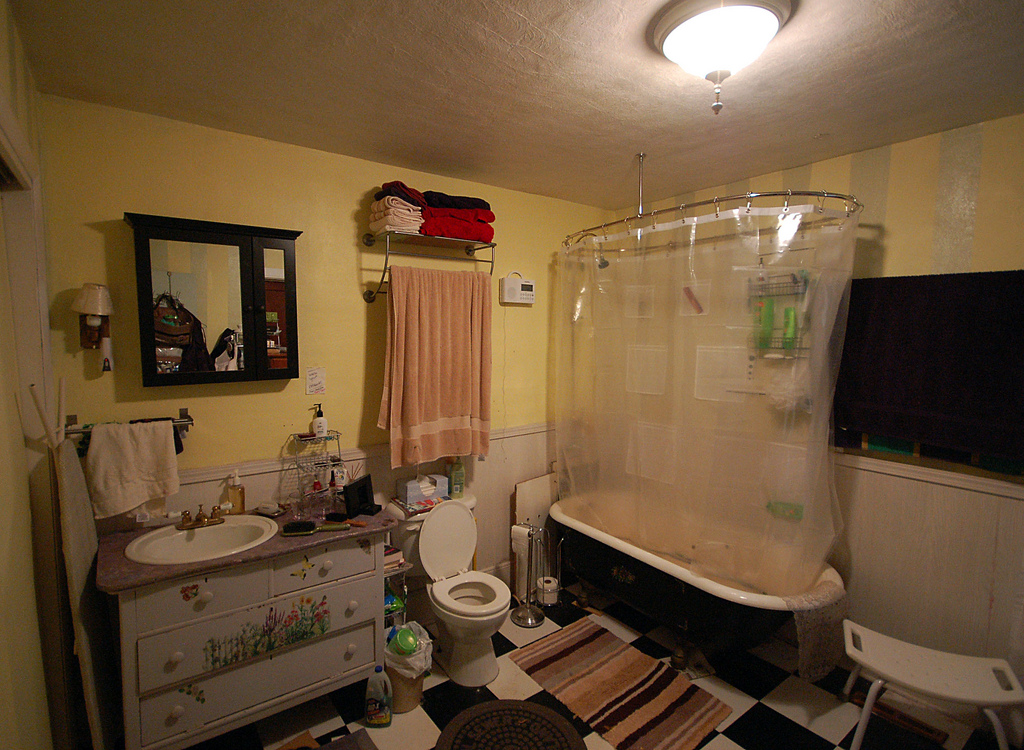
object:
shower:
[544, 192, 867, 667]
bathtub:
[547, 494, 845, 653]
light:
[69, 283, 115, 373]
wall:
[36, 87, 617, 634]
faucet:
[173, 503, 223, 530]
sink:
[124, 513, 278, 565]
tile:
[417, 678, 500, 732]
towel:
[377, 264, 492, 469]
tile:
[498, 603, 563, 648]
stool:
[840, 617, 1023, 750]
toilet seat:
[429, 569, 509, 616]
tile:
[720, 702, 835, 750]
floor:
[213, 582, 1024, 750]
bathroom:
[0, 0, 1024, 750]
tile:
[485, 647, 543, 702]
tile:
[688, 673, 757, 735]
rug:
[506, 614, 738, 749]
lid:
[419, 500, 477, 582]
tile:
[748, 635, 806, 675]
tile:
[759, 673, 861, 745]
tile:
[931, 123, 986, 276]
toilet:
[381, 490, 512, 686]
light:
[644, 0, 794, 117]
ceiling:
[0, 0, 1024, 213]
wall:
[611, 113, 1024, 658]